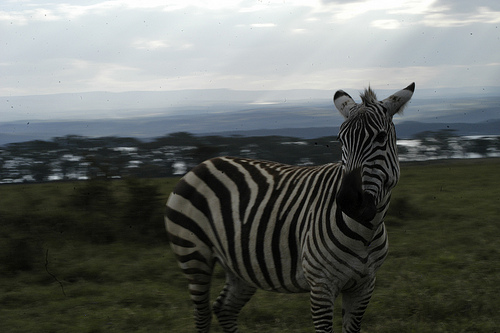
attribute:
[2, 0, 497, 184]
background — blurry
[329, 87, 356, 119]
ear — black, white, small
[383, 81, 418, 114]
ear — long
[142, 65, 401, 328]
animal — white, black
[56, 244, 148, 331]
grass — green, long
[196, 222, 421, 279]
belly — big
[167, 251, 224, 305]
thigh — skinny, black, white, striped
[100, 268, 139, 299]
grass — green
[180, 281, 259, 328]
legs — long, skinny, black, white, striped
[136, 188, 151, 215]
leaves — green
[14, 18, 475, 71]
sky — blue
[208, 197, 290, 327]
belly — round, large, black, white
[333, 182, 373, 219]
nose — black, small, round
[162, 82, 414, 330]
zebra — motionless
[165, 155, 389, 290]
body — black, white